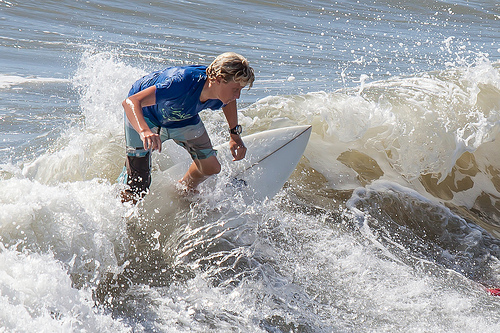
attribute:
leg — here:
[114, 148, 160, 222]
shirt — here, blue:
[121, 51, 214, 129]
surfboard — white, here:
[119, 121, 375, 277]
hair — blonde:
[200, 52, 284, 99]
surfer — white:
[122, 58, 256, 204]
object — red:
[477, 277, 498, 293]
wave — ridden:
[305, 50, 447, 209]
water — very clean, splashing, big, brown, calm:
[258, 7, 367, 86]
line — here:
[233, 128, 311, 189]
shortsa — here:
[107, 113, 224, 179]